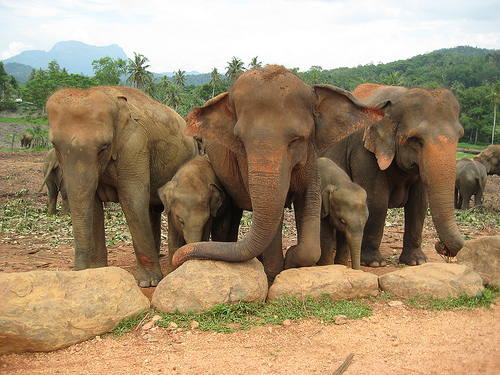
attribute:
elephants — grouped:
[49, 66, 489, 277]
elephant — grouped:
[132, 147, 272, 257]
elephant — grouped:
[286, 172, 436, 262]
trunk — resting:
[178, 227, 281, 273]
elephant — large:
[215, 58, 345, 262]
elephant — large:
[45, 65, 228, 251]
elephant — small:
[102, 139, 253, 234]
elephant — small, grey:
[139, 159, 229, 264]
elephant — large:
[168, 52, 415, 292]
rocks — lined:
[14, 264, 498, 304]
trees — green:
[18, 51, 498, 125]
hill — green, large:
[362, 24, 482, 124]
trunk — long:
[229, 172, 289, 252]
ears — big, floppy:
[176, 66, 370, 171]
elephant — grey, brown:
[26, 110, 229, 237]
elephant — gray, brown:
[201, 54, 354, 256]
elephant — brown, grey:
[279, 125, 426, 277]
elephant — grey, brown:
[349, 49, 493, 251]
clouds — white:
[159, 13, 376, 68]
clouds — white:
[212, 25, 400, 55]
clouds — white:
[159, 8, 239, 55]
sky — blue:
[72, 0, 488, 116]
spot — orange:
[421, 128, 470, 209]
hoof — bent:
[274, 228, 328, 280]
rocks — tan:
[45, 253, 492, 298]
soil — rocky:
[227, 315, 363, 371]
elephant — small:
[148, 146, 240, 286]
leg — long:
[118, 184, 170, 294]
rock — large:
[270, 268, 380, 298]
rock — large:
[387, 259, 497, 306]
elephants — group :
[49, 60, 478, 250]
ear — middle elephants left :
[314, 87, 366, 163]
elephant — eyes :
[43, 56, 482, 275]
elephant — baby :
[32, 45, 462, 278]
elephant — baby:
[38, 63, 468, 282]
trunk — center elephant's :
[179, 137, 321, 268]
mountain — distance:
[11, 7, 141, 67]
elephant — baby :
[169, 54, 374, 269]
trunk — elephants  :
[150, 136, 297, 258]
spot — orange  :
[245, 149, 277, 178]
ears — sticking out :
[184, 60, 390, 149]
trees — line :
[44, 47, 306, 93]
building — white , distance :
[5, 90, 46, 105]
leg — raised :
[283, 191, 338, 269]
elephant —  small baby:
[317, 157, 379, 273]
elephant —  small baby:
[314, 150, 376, 261]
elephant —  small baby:
[314, 156, 398, 273]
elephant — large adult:
[29, 90, 185, 253]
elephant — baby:
[159, 150, 226, 229]